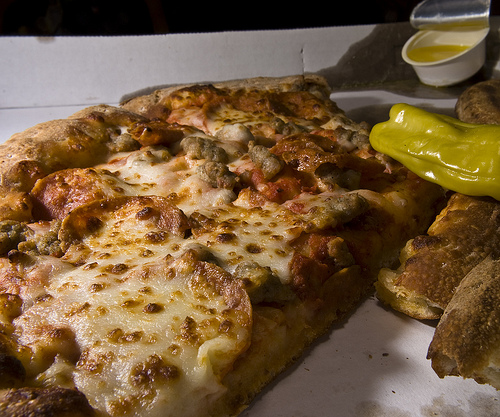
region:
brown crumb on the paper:
[358, 340, 413, 384]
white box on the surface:
[312, 366, 377, 401]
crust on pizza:
[418, 293, 492, 365]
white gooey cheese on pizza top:
[103, 320, 165, 372]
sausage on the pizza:
[175, 133, 237, 179]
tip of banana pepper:
[355, 107, 412, 150]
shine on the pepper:
[418, 124, 454, 161]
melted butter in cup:
[420, 36, 454, 58]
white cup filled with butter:
[382, 28, 477, 93]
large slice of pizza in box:
[33, 79, 409, 351]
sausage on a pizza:
[179, 136, 239, 191]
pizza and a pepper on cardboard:
[1, 75, 498, 415]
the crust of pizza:
[0, 102, 127, 204]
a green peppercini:
[365, 101, 499, 200]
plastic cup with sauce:
[398, 28, 489, 90]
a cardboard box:
[0, 16, 403, 68]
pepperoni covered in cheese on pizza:
[60, 192, 184, 247]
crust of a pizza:
[424, 253, 498, 383]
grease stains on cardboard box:
[355, 393, 498, 415]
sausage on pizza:
[326, 193, 370, 219]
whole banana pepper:
[366, 101, 498, 203]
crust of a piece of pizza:
[422, 252, 496, 381]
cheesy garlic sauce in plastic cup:
[398, 0, 492, 90]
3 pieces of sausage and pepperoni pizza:
[0, 69, 447, 414]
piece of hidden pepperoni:
[58, 194, 185, 236]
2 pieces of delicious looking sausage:
[178, 133, 239, 190]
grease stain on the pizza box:
[315, 19, 419, 96]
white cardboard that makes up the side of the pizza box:
[0, 33, 304, 88]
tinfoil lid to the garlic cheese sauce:
[408, 1, 491, 33]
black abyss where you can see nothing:
[1, 0, 413, 35]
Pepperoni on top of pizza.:
[58, 196, 188, 247]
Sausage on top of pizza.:
[178, 137, 223, 159]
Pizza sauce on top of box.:
[399, 26, 493, 83]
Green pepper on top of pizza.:
[372, 107, 499, 199]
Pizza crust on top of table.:
[427, 259, 493, 389]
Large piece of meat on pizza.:
[301, 192, 368, 228]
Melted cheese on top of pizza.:
[74, 283, 228, 412]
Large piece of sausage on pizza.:
[298, 190, 368, 236]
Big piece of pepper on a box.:
[369, 107, 499, 199]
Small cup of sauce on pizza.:
[405, 23, 490, 90]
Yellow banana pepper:
[373, 96, 498, 204]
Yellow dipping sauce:
[396, 8, 495, 89]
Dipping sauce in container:
[405, 4, 497, 94]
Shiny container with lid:
[394, 5, 496, 95]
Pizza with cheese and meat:
[11, 86, 361, 415]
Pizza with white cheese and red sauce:
[3, 61, 368, 415]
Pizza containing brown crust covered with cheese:
[2, 99, 325, 403]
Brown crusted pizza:
[385, 198, 497, 384]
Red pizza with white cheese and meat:
[2, 85, 393, 412]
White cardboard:
[322, 326, 421, 415]